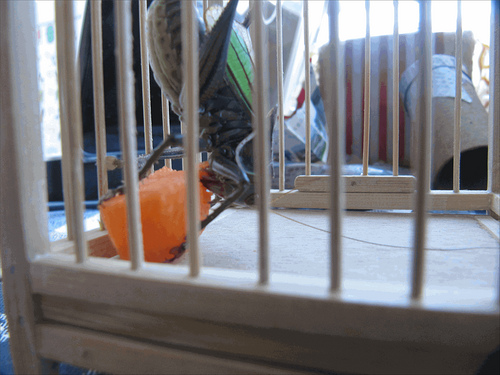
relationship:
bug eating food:
[149, 0, 314, 239] [101, 164, 196, 254]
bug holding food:
[102, 0, 268, 273] [101, 164, 196, 254]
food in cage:
[101, 164, 196, 254] [4, 6, 484, 367]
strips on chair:
[344, 36, 455, 165] [320, 34, 473, 176]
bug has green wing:
[96, 0, 280, 270] [191, 0, 258, 105]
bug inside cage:
[93, 0, 343, 259] [4, 6, 484, 367]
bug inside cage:
[112, 0, 283, 258] [4, 6, 484, 367]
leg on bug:
[169, 185, 250, 259] [102, 0, 268, 273]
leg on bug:
[116, 126, 208, 190] [102, 0, 268, 273]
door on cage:
[282, 31, 433, 203] [4, 6, 484, 367]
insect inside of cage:
[0, 0, 500, 373] [132, 0, 492, 297]